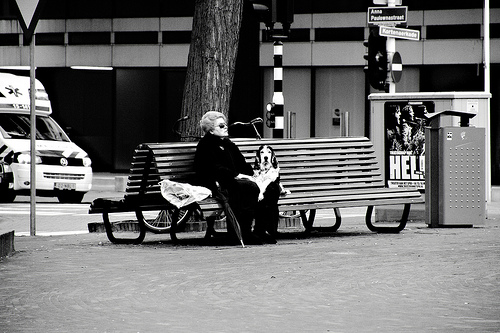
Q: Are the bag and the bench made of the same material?
A: No, the bag is made of plastic and the bench is made of wood.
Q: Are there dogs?
A: Yes, there is a dog.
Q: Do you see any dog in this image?
A: Yes, there is a dog.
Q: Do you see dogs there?
A: Yes, there is a dog.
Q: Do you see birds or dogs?
A: Yes, there is a dog.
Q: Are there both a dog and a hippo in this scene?
A: No, there is a dog but no hippos.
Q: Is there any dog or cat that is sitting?
A: Yes, the dog is sitting.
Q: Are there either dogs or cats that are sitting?
A: Yes, the dog is sitting.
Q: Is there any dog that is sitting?
A: Yes, there is a dog that is sitting.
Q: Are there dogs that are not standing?
A: Yes, there is a dog that is sitting.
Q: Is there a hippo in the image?
A: No, there are no hippos.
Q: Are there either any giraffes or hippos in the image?
A: No, there are no hippos or giraffes.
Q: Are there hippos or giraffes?
A: No, there are no hippos or giraffes.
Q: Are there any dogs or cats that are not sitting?
A: No, there is a dog but it is sitting.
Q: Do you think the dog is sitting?
A: Yes, the dog is sitting.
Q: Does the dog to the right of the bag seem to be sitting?
A: Yes, the dog is sitting.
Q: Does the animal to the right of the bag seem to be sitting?
A: Yes, the dog is sitting.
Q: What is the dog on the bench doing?
A: The dog is sitting.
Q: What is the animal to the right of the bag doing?
A: The dog is sitting.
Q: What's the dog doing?
A: The dog is sitting.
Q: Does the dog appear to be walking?
A: No, the dog is sitting.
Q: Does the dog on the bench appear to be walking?
A: No, the dog is sitting.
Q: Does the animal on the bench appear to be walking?
A: No, the dog is sitting.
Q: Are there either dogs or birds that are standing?
A: No, there is a dog but it is sitting.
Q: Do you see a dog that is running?
A: No, there is a dog but it is sitting.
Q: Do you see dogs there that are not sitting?
A: No, there is a dog but it is sitting.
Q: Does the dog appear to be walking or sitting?
A: The dog is sitting.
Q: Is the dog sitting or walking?
A: The dog is sitting.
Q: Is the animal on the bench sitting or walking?
A: The dog is sitting.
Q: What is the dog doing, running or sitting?
A: The dog is sitting.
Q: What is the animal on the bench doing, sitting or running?
A: The dog is sitting.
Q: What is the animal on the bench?
A: The animal is a dog.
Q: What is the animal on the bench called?
A: The animal is a dog.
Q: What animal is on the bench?
A: The animal is a dog.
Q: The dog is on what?
A: The dog is on the bench.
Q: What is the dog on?
A: The dog is on the bench.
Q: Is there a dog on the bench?
A: Yes, there is a dog on the bench.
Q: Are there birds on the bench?
A: No, there is a dog on the bench.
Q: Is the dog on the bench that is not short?
A: Yes, the dog is on the bench.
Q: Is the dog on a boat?
A: No, the dog is on the bench.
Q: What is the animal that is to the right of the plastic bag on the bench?
A: The animal is a dog.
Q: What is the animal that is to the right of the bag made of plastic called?
A: The animal is a dog.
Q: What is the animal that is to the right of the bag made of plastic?
A: The animal is a dog.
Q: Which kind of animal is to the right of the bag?
A: The animal is a dog.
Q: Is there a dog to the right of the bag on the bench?
A: Yes, there is a dog to the right of the bag.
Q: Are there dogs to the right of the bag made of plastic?
A: Yes, there is a dog to the right of the bag.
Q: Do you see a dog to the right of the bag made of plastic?
A: Yes, there is a dog to the right of the bag.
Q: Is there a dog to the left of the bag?
A: No, the dog is to the right of the bag.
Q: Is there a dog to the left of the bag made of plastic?
A: No, the dog is to the right of the bag.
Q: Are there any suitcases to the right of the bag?
A: No, there is a dog to the right of the bag.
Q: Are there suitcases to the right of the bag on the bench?
A: No, there is a dog to the right of the bag.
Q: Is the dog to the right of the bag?
A: Yes, the dog is to the right of the bag.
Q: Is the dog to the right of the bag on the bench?
A: Yes, the dog is to the right of the bag.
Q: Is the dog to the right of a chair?
A: No, the dog is to the right of the bag.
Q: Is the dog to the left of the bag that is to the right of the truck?
A: No, the dog is to the right of the bag.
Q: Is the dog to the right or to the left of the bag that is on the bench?
A: The dog is to the right of the bag.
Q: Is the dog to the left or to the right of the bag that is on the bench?
A: The dog is to the right of the bag.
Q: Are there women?
A: Yes, there is a woman.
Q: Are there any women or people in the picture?
A: Yes, there is a woman.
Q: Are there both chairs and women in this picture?
A: No, there is a woman but no chairs.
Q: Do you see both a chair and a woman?
A: No, there is a woman but no chairs.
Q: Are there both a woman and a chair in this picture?
A: No, there is a woman but no chairs.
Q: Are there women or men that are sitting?
A: Yes, the woman is sitting.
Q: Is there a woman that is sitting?
A: Yes, there is a woman that is sitting.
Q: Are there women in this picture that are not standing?
A: Yes, there is a woman that is sitting.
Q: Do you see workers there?
A: No, there are no workers.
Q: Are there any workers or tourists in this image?
A: No, there are no workers or tourists.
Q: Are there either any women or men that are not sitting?
A: No, there is a woman but she is sitting.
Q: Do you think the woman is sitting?
A: Yes, the woman is sitting.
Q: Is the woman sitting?
A: Yes, the woman is sitting.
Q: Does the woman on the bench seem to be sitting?
A: Yes, the woman is sitting.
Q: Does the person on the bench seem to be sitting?
A: Yes, the woman is sitting.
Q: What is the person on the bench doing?
A: The woman is sitting.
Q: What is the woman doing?
A: The woman is sitting.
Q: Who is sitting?
A: The woman is sitting.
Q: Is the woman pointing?
A: No, the woman is sitting.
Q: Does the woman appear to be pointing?
A: No, the woman is sitting.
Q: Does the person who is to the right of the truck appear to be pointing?
A: No, the woman is sitting.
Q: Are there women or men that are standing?
A: No, there is a woman but she is sitting.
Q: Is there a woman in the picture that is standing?
A: No, there is a woman but she is sitting.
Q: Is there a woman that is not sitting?
A: No, there is a woman but she is sitting.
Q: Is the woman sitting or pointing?
A: The woman is sitting.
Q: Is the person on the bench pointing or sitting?
A: The woman is sitting.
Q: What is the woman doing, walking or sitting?
A: The woman is sitting.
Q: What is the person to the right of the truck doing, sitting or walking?
A: The woman is sitting.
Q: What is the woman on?
A: The woman is on the bench.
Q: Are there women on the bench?
A: Yes, there is a woman on the bench.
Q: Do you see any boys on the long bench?
A: No, there is a woman on the bench.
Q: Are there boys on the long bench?
A: No, there is a woman on the bench.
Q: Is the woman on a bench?
A: Yes, the woman is on a bench.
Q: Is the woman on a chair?
A: No, the woman is on a bench.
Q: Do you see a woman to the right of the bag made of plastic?
A: Yes, there is a woman to the right of the bag.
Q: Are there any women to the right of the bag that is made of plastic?
A: Yes, there is a woman to the right of the bag.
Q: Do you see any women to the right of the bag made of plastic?
A: Yes, there is a woman to the right of the bag.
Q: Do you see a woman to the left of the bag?
A: No, the woman is to the right of the bag.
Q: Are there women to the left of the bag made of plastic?
A: No, the woman is to the right of the bag.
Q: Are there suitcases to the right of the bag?
A: No, there is a woman to the right of the bag.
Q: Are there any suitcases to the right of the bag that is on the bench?
A: No, there is a woman to the right of the bag.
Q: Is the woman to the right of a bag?
A: Yes, the woman is to the right of a bag.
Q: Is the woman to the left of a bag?
A: No, the woman is to the right of a bag.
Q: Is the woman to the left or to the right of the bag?
A: The woman is to the right of the bag.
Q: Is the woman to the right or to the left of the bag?
A: The woman is to the right of the bag.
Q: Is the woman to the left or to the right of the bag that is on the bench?
A: The woman is to the right of the bag.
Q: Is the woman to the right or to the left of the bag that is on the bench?
A: The woman is to the right of the bag.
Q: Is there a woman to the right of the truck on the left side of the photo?
A: Yes, there is a woman to the right of the truck.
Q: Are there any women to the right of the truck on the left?
A: Yes, there is a woman to the right of the truck.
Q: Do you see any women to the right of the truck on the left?
A: Yes, there is a woman to the right of the truck.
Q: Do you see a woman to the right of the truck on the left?
A: Yes, there is a woman to the right of the truck.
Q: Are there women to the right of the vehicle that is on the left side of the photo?
A: Yes, there is a woman to the right of the truck.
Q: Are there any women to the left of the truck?
A: No, the woman is to the right of the truck.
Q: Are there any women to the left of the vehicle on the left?
A: No, the woman is to the right of the truck.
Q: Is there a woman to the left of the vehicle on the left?
A: No, the woman is to the right of the truck.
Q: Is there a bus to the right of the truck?
A: No, there is a woman to the right of the truck.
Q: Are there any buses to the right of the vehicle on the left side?
A: No, there is a woman to the right of the truck.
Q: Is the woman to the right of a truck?
A: Yes, the woman is to the right of a truck.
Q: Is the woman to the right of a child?
A: No, the woman is to the right of a truck.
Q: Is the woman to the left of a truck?
A: No, the woman is to the right of a truck.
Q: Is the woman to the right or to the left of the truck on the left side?
A: The woman is to the right of the truck.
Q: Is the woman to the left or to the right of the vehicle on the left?
A: The woman is to the right of the truck.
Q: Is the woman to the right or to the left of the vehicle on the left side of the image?
A: The woman is to the right of the truck.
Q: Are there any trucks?
A: Yes, there is a truck.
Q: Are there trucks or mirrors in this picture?
A: Yes, there is a truck.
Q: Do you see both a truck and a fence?
A: No, there is a truck but no fences.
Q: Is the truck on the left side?
A: Yes, the truck is on the left of the image.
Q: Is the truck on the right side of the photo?
A: No, the truck is on the left of the image.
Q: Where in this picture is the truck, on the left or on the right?
A: The truck is on the left of the image.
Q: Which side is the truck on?
A: The truck is on the left of the image.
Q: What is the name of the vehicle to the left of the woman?
A: The vehicle is a truck.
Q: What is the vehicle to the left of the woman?
A: The vehicle is a truck.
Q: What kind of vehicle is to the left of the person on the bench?
A: The vehicle is a truck.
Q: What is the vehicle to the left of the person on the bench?
A: The vehicle is a truck.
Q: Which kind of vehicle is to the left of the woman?
A: The vehicle is a truck.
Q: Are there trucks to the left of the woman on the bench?
A: Yes, there is a truck to the left of the woman.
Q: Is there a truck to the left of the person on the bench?
A: Yes, there is a truck to the left of the woman.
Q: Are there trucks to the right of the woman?
A: No, the truck is to the left of the woman.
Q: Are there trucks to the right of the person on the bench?
A: No, the truck is to the left of the woman.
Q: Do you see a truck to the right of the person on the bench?
A: No, the truck is to the left of the woman.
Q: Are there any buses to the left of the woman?
A: No, there is a truck to the left of the woman.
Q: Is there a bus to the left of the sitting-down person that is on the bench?
A: No, there is a truck to the left of the woman.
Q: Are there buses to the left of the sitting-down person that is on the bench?
A: No, there is a truck to the left of the woman.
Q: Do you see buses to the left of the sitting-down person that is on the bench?
A: No, there is a truck to the left of the woman.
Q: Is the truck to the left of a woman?
A: Yes, the truck is to the left of a woman.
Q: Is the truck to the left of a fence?
A: No, the truck is to the left of a woman.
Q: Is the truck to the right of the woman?
A: No, the truck is to the left of the woman.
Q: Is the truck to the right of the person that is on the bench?
A: No, the truck is to the left of the woman.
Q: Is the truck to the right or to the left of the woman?
A: The truck is to the left of the woman.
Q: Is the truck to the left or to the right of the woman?
A: The truck is to the left of the woman.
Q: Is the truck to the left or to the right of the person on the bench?
A: The truck is to the left of the woman.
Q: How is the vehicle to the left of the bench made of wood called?
A: The vehicle is a truck.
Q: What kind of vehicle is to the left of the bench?
A: The vehicle is a truck.